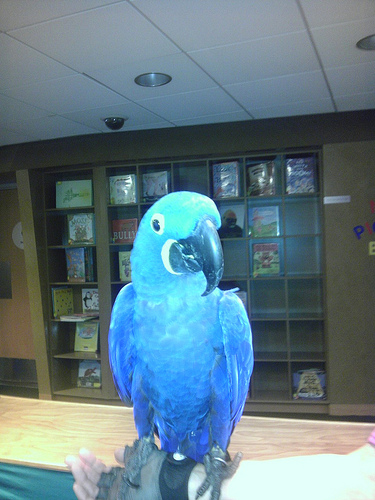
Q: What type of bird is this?
A: Parrot.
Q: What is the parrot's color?
A: Blue.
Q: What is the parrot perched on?
A: Arm.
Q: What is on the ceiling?
A: Tiles.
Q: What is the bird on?
A: An arm.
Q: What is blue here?
A: Bird.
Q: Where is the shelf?
A: In the wall.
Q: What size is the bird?
A: Large.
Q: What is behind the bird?
A: Shelves.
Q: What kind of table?
A: Wood.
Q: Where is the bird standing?
A: On the person's arm.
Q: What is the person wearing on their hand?
A: A glove.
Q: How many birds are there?
A: 1.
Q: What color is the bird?
A: Blue.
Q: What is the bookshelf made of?
A: Wood.